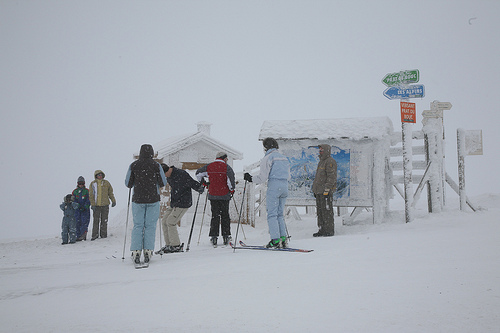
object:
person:
[154, 161, 206, 256]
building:
[132, 121, 244, 225]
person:
[195, 151, 236, 248]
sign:
[382, 68, 418, 85]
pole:
[402, 96, 411, 223]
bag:
[0, 0, 499, 208]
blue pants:
[130, 203, 160, 251]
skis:
[121, 186, 132, 260]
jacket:
[251, 146, 291, 183]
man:
[195, 151, 237, 248]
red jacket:
[195, 158, 235, 201]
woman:
[229, 135, 315, 253]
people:
[88, 169, 117, 241]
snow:
[298, 262, 450, 323]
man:
[244, 137, 292, 251]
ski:
[227, 241, 312, 253]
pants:
[130, 202, 162, 252]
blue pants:
[265, 179, 292, 239]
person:
[59, 194, 81, 245]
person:
[69, 175, 89, 242]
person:
[123, 143, 168, 269]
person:
[312, 143, 337, 237]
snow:
[276, 119, 391, 138]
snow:
[158, 130, 193, 146]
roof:
[258, 114, 388, 139]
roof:
[154, 120, 243, 161]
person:
[155, 157, 205, 257]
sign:
[379, 82, 431, 102]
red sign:
[399, 100, 417, 122]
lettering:
[401, 103, 414, 119]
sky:
[3, 7, 380, 116]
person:
[243, 136, 291, 251]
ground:
[0, 193, 500, 332]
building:
[257, 115, 396, 227]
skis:
[206, 235, 232, 248]